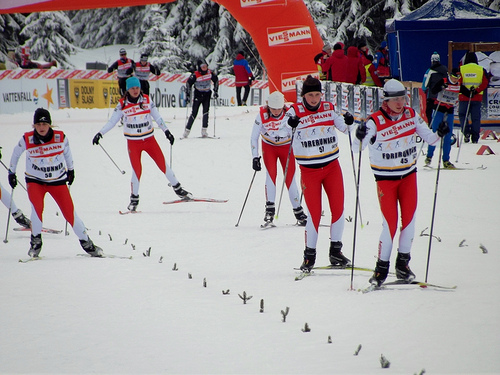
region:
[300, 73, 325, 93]
Black beanie cap on a person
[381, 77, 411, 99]
Black and white beanie cap on a person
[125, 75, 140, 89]
Light blue colored beanie cap on a person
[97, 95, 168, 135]
White, red and black long sleeve shirt on a person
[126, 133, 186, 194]
Red and white pants on a person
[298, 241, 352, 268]
Black ski Shoes on a person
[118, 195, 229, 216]
Red and white ski's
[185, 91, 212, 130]
Black pants on a person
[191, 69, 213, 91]
Red, white ans black vest on a person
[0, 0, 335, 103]
Red and white sign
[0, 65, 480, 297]
competitors involved in a race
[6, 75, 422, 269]
five individuals wearing identical uniforms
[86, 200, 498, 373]
small dividers in the snow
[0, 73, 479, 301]
competitors are all wearing skis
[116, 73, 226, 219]
person's left foot in the air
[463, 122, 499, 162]
small red triangular objects on the snow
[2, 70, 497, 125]
advertisements covering barrier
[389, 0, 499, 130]
blue tent behind barrier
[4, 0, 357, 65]
snow on trees beyond barrier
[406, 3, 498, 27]
snow on roof of tent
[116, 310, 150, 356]
the snow is white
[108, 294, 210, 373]
the snow is white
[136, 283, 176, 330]
the snow is white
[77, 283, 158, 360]
the snow is white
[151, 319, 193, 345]
the snow is white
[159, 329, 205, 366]
the snow is white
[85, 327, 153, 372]
the snow is white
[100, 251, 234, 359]
the snow is white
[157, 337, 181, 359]
the snow is white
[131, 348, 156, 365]
the snow is white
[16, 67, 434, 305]
Group of people skiing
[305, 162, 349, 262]
Wearing red and white pants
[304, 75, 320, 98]
Black ski hat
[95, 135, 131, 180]
Ski pole is skinny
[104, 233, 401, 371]
Line in snow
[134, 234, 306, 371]
Snow is white and diffuse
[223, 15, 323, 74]
Red sign in background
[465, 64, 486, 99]
Wearing yellow vest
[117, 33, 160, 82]
Two people behind skier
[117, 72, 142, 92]
Wearing blue cap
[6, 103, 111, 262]
a cross country skier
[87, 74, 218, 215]
a cross country skier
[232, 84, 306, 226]
a cross country skier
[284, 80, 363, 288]
a cross country skier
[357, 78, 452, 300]
a cross country skier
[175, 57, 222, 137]
a cross country skier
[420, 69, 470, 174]
a cross country skier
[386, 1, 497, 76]
a blue pop up tent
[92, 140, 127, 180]
a black ski pole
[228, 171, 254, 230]
a black ski pole